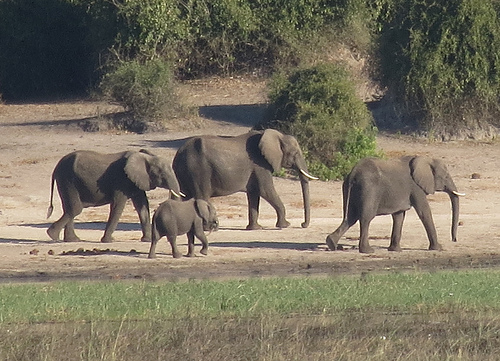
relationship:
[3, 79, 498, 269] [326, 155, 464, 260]
brown dirt under elephants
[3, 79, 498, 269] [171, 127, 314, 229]
brown dirt under elephants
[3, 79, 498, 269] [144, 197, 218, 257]
brown dirt under elephants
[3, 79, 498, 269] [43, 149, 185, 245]
brown dirt under elephants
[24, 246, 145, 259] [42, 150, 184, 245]
pile beside elephant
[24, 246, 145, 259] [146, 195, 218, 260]
pile beside elephant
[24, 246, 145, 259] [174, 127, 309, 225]
pile beside elephant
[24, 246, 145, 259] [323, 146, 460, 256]
pile beside elephant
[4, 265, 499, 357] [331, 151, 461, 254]
grass beside elephant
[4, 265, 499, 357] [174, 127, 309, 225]
grass beside elephant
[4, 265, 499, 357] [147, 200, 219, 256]
grass beside elephant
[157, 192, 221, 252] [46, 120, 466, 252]
baby elephant in herd